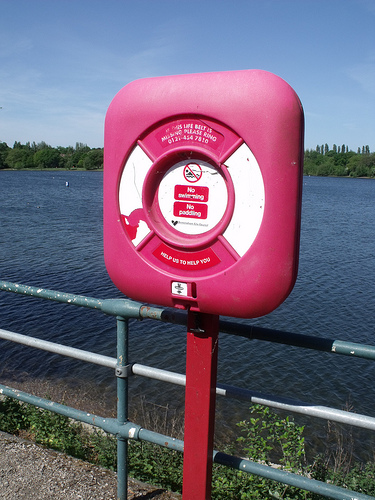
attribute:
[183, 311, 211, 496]
stand — red, metal, pink, wooden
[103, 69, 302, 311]
sign — large, pink, rounded, small, curved, red, square, white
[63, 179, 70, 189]
buoy — floating, small, white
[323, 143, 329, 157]
tree — large, green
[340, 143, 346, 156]
tree — large, green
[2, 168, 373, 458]
water — dark, blue, calm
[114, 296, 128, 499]
pole — horizontal, green, metal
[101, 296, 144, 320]
attachment — grey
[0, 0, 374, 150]
sky — blue, clear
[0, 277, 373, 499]
handrails — for safety, blue, metal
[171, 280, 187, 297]
label — white, small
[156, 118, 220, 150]
letters — white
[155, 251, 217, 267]
writing — white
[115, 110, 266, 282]
diagram — circular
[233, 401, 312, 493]
weeds — green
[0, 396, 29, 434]
plant — green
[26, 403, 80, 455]
plant — green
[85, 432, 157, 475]
plant — green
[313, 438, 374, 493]
plant — green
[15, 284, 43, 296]
paint — chipped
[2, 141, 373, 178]
area — wooded